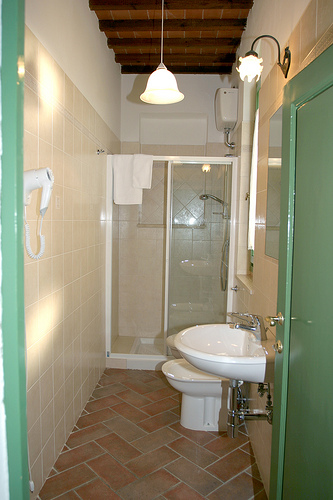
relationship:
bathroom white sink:
[28, 1, 281, 493] [168, 323, 271, 381]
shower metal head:
[115, 158, 228, 369] [198, 192, 234, 217]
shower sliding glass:
[115, 158, 228, 369] [166, 162, 232, 338]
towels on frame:
[113, 152, 151, 203] [108, 156, 169, 360]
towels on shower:
[113, 152, 151, 203] [115, 158, 228, 369]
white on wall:
[22, 167, 55, 260] [26, 37, 114, 490]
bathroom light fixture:
[28, 1, 281, 493] [142, 3, 182, 113]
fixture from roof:
[139, 0, 186, 105] [93, 1, 248, 73]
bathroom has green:
[28, 1, 281, 493] [267, 47, 332, 499]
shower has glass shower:
[115, 158, 228, 369] [111, 160, 235, 358]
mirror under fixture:
[264, 108, 280, 259] [139, 0, 186, 105]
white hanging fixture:
[139, 62, 185, 104] [142, 3, 182, 113]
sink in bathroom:
[168, 323, 271, 381] [28, 1, 281, 493]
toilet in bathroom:
[162, 362, 235, 435] [28, 1, 281, 493]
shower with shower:
[115, 158, 228, 369] [111, 160, 235, 358]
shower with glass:
[115, 158, 228, 369] [114, 165, 228, 352]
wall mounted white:
[26, 37, 114, 490] [22, 167, 55, 260]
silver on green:
[265, 312, 284, 328] [267, 47, 332, 499]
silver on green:
[265, 311, 282, 356] [267, 47, 332, 499]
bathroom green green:
[28, 1, 281, 493] [267, 47, 332, 499]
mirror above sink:
[264, 108, 280, 259] [168, 323, 271, 381]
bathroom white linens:
[28, 1, 281, 493] [113, 152, 151, 203]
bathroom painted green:
[28, 1, 281, 493] [267, 47, 332, 499]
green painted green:
[270, 50, 332, 498] [267, 47, 332, 499]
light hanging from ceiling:
[142, 3, 182, 113] [93, 1, 248, 73]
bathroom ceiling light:
[28, 1, 281, 493] [142, 3, 182, 113]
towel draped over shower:
[113, 152, 151, 203] [115, 158, 228, 369]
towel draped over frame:
[113, 152, 151, 203] [108, 156, 169, 360]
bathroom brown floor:
[28, 1, 281, 493] [37, 368, 269, 499]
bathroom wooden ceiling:
[28, 1, 281, 493] [93, 1, 248, 73]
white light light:
[141, 66, 187, 108] [142, 3, 182, 113]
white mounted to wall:
[22, 167, 55, 260] [26, 37, 114, 490]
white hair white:
[24, 164, 51, 260] [22, 167, 55, 260]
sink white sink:
[174, 323, 267, 384] [168, 323, 271, 381]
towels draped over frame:
[113, 152, 151, 203] [107, 156, 169, 359]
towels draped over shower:
[113, 152, 151, 203] [115, 158, 228, 369]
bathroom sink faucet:
[28, 1, 281, 493] [228, 306, 264, 340]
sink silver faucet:
[168, 323, 271, 381] [228, 306, 264, 340]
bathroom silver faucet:
[28, 1, 281, 493] [228, 306, 264, 340]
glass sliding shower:
[114, 165, 228, 352] [111, 160, 235, 358]